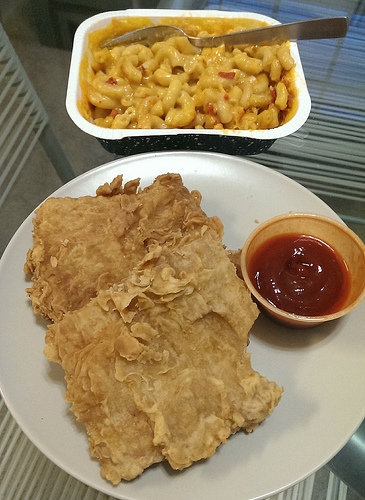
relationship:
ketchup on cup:
[244, 229, 363, 318] [240, 213, 365, 331]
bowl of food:
[66, 8, 311, 154] [109, 31, 244, 72]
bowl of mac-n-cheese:
[66, 8, 311, 154] [91, 30, 288, 128]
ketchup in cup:
[247, 232, 351, 317] [216, 212, 362, 346]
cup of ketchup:
[240, 213, 364, 330] [252, 233, 352, 316]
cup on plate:
[240, 213, 364, 330] [2, 150, 352, 499]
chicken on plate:
[23, 172, 284, 486] [2, 150, 352, 499]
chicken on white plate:
[23, 172, 284, 486] [0, 149, 363, 329]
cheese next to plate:
[113, 53, 262, 103] [290, 370, 334, 441]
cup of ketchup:
[240, 213, 365, 331] [247, 231, 354, 319]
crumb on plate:
[244, 207, 265, 227] [2, 150, 352, 499]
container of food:
[48, 27, 279, 154] [118, 41, 342, 163]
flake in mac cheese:
[216, 71, 237, 79] [94, 21, 289, 128]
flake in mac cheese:
[204, 102, 213, 114] [94, 21, 289, 128]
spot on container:
[187, 134, 205, 147] [64, 5, 320, 147]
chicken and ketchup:
[43, 213, 250, 436] [250, 215, 330, 303]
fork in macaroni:
[100, 15, 348, 51] [98, 27, 290, 118]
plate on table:
[7, 171, 329, 498] [3, 2, 361, 494]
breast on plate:
[26, 167, 284, 485] [2, 150, 352, 499]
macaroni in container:
[87, 25, 295, 129] [49, 95, 293, 146]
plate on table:
[0, 150, 365, 500] [3, 2, 361, 494]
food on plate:
[92, 19, 283, 123] [0, 150, 365, 500]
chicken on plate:
[23, 172, 284, 486] [0, 150, 365, 500]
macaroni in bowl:
[94, 57, 271, 114] [66, 8, 311, 154]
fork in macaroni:
[99, 13, 351, 53] [92, 40, 283, 122]